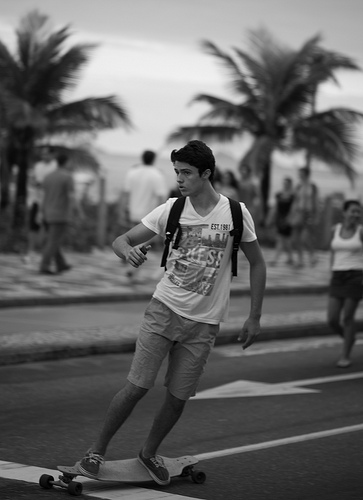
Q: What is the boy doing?
A: Skateboarding.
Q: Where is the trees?
A: Background.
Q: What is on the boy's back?
A: Backpack.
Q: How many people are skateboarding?
A: One.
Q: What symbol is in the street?
A: Arrow.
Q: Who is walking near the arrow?
A: Lady.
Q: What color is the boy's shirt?
A: White.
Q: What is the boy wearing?
A: Shorts.